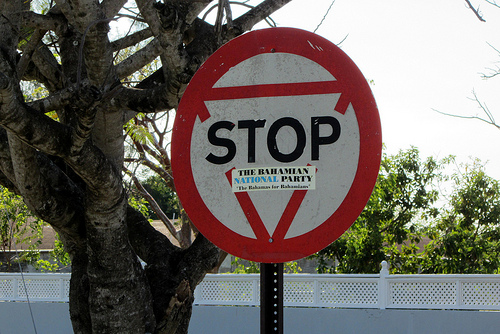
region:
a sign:
[159, 33, 374, 295]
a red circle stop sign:
[160, 23, 392, 329]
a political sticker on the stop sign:
[230, 161, 362, 211]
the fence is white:
[10, 268, 498, 311]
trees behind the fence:
[292, 154, 494, 296]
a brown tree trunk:
[0, 1, 272, 331]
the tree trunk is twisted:
[12, 0, 321, 317]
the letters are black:
[208, 104, 348, 167]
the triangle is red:
[186, 78, 355, 247]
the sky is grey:
[270, 0, 497, 202]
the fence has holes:
[0, 269, 491, 316]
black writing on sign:
[197, 117, 348, 164]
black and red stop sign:
[147, 25, 414, 284]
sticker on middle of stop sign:
[222, 162, 322, 197]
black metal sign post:
[257, 267, 289, 332]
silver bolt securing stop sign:
[263, 233, 273, 249]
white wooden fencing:
[301, 267, 498, 312]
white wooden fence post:
[368, 257, 395, 308]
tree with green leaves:
[406, 173, 498, 275]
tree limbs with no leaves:
[35, 0, 120, 188]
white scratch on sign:
[293, 32, 337, 67]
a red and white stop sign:
[166, 25, 384, 265]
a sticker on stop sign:
[229, 163, 317, 194]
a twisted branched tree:
[0, 0, 292, 332]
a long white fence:
[0, 258, 499, 309]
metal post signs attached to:
[256, 263, 285, 332]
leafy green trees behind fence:
[323, 143, 498, 271]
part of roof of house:
[0, 213, 61, 252]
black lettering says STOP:
[205, 115, 343, 165]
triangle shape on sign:
[194, 78, 352, 240]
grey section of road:
[0, 298, 498, 332]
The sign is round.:
[163, 25, 389, 267]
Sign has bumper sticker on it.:
[162, 27, 388, 277]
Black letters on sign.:
[158, 22, 396, 264]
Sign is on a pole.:
[163, 10, 393, 329]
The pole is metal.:
[251, 256, 294, 332]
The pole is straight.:
[256, 255, 288, 331]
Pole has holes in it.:
[251, 246, 297, 331]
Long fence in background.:
[1, 267, 498, 317]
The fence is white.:
[0, 259, 498, 316]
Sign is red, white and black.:
[161, 24, 387, 266]